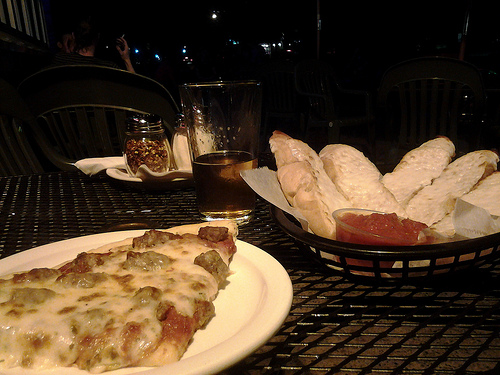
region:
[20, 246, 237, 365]
pizza on the plate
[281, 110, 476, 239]
bread and dipping sauce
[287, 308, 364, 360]
the table is grated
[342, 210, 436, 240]
sauce in the container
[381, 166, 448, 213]
the bread is powdered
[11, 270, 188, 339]
sauce on the pizza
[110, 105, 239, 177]
the condiments are on the table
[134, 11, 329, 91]
the background is dark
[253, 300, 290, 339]
the plate is white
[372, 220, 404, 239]
the sauce is red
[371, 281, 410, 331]
part of a shade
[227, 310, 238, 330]
part of a plate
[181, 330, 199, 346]
edge of a pizza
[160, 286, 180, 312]
part f a food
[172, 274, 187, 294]
edge of a pizza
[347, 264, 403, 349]
part of a shade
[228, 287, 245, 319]
part of a plale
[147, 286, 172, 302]
topping on the pizza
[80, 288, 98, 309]
topping on the pizza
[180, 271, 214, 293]
topping on the pizza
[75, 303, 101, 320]
topping on the pizza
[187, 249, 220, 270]
topping on the pizza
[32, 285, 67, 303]
topping on the pizza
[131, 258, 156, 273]
topping on the pizza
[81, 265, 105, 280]
topping on the pizza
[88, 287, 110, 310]
topping on the pizza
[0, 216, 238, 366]
A slice of pizza on a white plate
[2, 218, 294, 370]
A plate of pizza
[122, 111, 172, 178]
A small shaker of red pepper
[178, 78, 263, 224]
A clear glass of amber liquid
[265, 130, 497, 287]
A basket of cheese bread and marinara sauce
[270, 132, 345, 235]
A slice of cheesy bread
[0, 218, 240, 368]
Sausage on a pizza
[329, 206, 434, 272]
A small cup of marinara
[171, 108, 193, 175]
A shaker full of parmesean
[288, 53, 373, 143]
A black plastic dining chair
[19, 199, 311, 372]
this is a dinner plate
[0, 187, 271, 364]
this is a slice of pizza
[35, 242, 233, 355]
sausage on a pizza slice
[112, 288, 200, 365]
red sauce on pizza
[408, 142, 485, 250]
this is a piece of bread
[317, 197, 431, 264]
red sauce in cup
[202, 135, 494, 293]
sliced bread in basket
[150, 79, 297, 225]
this is a drinking glass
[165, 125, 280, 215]
drinking glass is half full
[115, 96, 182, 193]
this is a pepper shaker